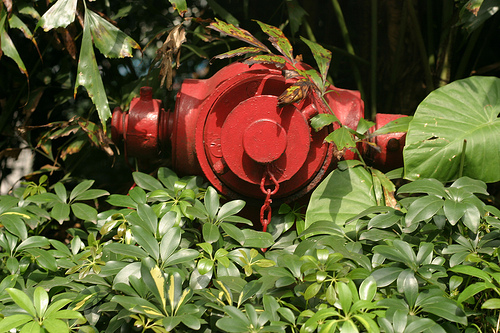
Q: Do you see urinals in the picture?
A: No, there are no urinals.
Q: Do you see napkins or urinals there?
A: No, there are no urinals or napkins.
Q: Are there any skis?
A: No, there are no skis.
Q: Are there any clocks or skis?
A: No, there are no skis or clocks.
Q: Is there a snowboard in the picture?
A: No, there are no snowboards.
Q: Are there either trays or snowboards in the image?
A: No, there are no snowboards or trays.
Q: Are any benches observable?
A: No, there are no benches.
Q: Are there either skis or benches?
A: No, there are no benches or skis.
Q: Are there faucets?
A: No, there are no faucets.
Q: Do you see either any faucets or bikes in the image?
A: No, there are no faucets or bikes.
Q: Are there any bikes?
A: No, there are no bikes.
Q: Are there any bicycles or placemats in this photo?
A: No, there are no bicycles or placemats.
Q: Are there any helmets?
A: No, there are no helmets.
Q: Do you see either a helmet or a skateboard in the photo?
A: No, there are no helmets or skateboards.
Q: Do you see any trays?
A: No, there are no trays.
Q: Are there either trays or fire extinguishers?
A: No, there are no trays or fire extinguishers.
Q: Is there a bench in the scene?
A: No, there are no benches.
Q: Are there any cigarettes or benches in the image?
A: No, there are no benches or cigarettes.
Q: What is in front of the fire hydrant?
A: The bush is in front of the fire hydrant.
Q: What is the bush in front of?
A: The bush is in front of the fire hydrant.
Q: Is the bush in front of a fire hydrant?
A: Yes, the bush is in front of a fire hydrant.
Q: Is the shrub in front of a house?
A: No, the shrub is in front of a fire hydrant.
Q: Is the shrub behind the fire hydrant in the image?
A: No, the shrub is in front of the fire hydrant.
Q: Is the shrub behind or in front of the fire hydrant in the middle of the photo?
A: The shrub is in front of the hydrant.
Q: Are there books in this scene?
A: No, there are no books.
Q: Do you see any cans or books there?
A: No, there are no books or cans.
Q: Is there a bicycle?
A: No, there are no bicycles.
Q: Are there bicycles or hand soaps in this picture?
A: No, there are no bicycles or hand soaps.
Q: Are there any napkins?
A: No, there are no napkins.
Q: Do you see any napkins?
A: No, there are no napkins.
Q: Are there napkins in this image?
A: No, there are no napkins.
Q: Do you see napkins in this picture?
A: No, there are no napkins.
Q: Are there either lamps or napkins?
A: No, there are no napkins or lamps.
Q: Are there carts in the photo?
A: No, there are no carts.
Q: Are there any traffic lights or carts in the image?
A: No, there are no carts or traffic lights.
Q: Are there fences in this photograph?
A: No, there are no fences.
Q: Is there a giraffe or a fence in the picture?
A: No, there are no fences or giraffes.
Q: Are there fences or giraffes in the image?
A: No, there are no fences or giraffes.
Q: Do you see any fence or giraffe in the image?
A: No, there are no fences or giraffes.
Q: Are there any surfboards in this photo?
A: No, there are no surfboards.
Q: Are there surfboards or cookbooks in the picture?
A: No, there are no surfboards or cookbooks.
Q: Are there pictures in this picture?
A: No, there are no pictures.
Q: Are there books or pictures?
A: No, there are no pictures or books.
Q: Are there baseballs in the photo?
A: No, there are no baseballs.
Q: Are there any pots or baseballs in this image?
A: No, there are no baseballs or pots.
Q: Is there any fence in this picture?
A: No, there are no fences.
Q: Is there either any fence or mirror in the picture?
A: No, there are no fences or mirrors.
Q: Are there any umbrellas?
A: No, there are no umbrellas.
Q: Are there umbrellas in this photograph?
A: No, there are no umbrellas.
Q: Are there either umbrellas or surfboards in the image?
A: No, there are no umbrellas or surfboards.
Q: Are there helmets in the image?
A: No, there are no helmets.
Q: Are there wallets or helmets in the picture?
A: No, there are no helmets or wallets.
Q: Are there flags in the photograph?
A: No, there are no flags.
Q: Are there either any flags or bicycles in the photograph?
A: No, there are no flags or bicycles.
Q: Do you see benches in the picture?
A: No, there are no benches.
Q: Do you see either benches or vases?
A: No, there are no benches or vases.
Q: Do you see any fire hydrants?
A: Yes, there is a fire hydrant.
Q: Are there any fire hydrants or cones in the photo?
A: Yes, there is a fire hydrant.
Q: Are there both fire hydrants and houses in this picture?
A: No, there is a fire hydrant but no houses.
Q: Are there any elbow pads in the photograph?
A: No, there are no elbow pads.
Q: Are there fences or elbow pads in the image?
A: No, there are no elbow pads or fences.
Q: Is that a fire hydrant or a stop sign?
A: That is a fire hydrant.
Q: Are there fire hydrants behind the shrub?
A: Yes, there is a fire hydrant behind the shrub.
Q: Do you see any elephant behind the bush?
A: No, there is a fire hydrant behind the bush.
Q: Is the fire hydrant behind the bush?
A: Yes, the fire hydrant is behind the bush.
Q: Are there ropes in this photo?
A: No, there are no ropes.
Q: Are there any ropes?
A: No, there are no ropes.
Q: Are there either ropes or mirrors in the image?
A: No, there are no ropes or mirrors.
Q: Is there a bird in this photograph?
A: No, there are no birds.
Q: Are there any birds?
A: No, there are no birds.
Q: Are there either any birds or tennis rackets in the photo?
A: No, there are no birds or tennis rackets.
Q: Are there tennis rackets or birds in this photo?
A: No, there are no birds or tennis rackets.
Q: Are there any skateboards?
A: No, there are no skateboards.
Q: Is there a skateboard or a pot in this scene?
A: No, there are no skateboards or pots.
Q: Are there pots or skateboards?
A: No, there are no skateboards or pots.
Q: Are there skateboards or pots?
A: No, there are no skateboards or pots.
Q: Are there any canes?
A: No, there are no canes.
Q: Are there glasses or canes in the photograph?
A: No, there are no canes or glasses.